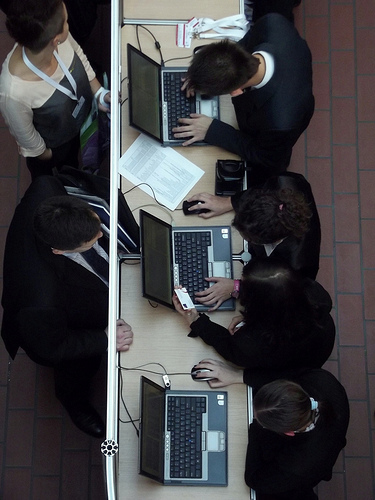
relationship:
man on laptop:
[170, 12, 315, 168] [124, 45, 216, 141]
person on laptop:
[197, 169, 326, 279] [140, 205, 232, 311]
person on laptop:
[177, 267, 337, 370] [140, 372, 235, 483]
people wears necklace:
[0, 0, 110, 195] [21, 47, 85, 118]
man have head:
[189, 358, 349, 496] [186, 40, 236, 75]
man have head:
[189, 358, 349, 496] [232, 184, 328, 246]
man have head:
[189, 358, 349, 496] [241, 271, 299, 302]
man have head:
[189, 358, 349, 496] [256, 378, 340, 420]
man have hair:
[170, 12, 315, 168] [183, 30, 262, 98]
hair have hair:
[32, 190, 101, 263] [224, 259, 310, 324]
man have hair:
[1, 180, 131, 436] [32, 190, 101, 263]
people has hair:
[0, 0, 110, 195] [1, 4, 82, 63]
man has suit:
[23, 195, 131, 431] [26, 240, 103, 398]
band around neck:
[12, 30, 106, 132] [12, 34, 74, 82]